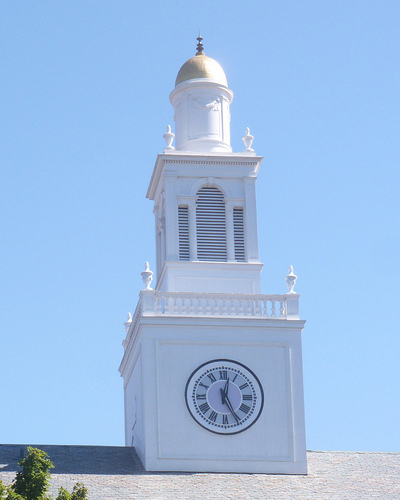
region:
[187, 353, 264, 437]
this is a clock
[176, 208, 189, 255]
this is a window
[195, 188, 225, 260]
this is a window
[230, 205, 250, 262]
this is a window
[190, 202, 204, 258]
this is a pillar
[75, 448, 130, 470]
this is a shadow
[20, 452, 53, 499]
this is a plant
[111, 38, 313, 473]
this s a bulding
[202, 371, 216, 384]
that is a roman number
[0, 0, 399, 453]
Very clear blue sky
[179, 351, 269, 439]
Large round clock on a white faced wall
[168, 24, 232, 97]
Brown dome shape with a pointed tip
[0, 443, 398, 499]
Rough grey roofing of a house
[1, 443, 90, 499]
Green leaves of a plant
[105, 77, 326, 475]
Clear white painted walls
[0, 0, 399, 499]
Building roof with a pillar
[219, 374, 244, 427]
Hands of a clock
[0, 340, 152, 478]
Wall and its shadow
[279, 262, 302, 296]
Small white painted monument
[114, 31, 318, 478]
it is white color building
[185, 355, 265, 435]
it is a circle clock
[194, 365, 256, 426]
roman letter timer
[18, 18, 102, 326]
sky color is blue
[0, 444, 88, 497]
it is a plant near this building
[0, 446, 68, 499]
it is green color plant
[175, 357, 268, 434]
clock is black and white color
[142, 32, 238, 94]
it is top of this building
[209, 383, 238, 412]
it is a center point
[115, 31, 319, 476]
white clock tower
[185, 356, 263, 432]
clock face on the tower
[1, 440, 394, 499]
roof the clock tower is on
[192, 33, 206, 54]
spire on the clock tower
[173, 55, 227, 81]
dome on the top of the clock tower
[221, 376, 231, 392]
hour hand of the clock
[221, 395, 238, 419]
minute hand of the clock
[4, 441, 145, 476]
shadow on the roof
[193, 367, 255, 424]
black roman numerals on the clockface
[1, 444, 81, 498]
tree top next to roof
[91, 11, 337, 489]
a white clock tower against a blue sky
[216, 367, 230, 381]
the number 12 of a clock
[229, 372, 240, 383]
the number 1 of a clock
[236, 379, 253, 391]
the number 2 of a clock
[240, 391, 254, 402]
the number 3 of a clock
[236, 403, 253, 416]
the number 4 of a clock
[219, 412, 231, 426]
the number 6 of a clock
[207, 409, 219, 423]
the number 7 of a clock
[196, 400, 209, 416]
the number 8 of a clock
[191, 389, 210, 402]
the number 9 of a clock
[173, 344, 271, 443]
clock on the tower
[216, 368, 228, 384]
roman numeral on the clock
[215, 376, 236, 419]
black hands on the clock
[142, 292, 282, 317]
white railing above the clock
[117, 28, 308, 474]
The clock is on the white tower.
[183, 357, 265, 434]
The numbers on the clock are black.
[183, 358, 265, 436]
The numbers on the clock are Roman numerals.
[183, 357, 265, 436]
The hands on the clock are black.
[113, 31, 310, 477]
The dome is on top of the tower.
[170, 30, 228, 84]
The dome is gold.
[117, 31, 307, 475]
There is an arch on the tower.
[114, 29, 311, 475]
There is a railing around the tower.